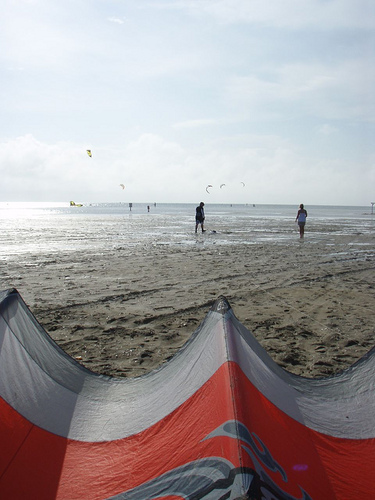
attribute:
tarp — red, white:
[1, 285, 373, 498]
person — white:
[296, 203, 307, 235]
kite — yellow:
[84, 144, 93, 156]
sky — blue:
[185, 11, 351, 168]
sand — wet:
[28, 236, 256, 260]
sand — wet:
[3, 219, 371, 383]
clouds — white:
[6, 26, 151, 104]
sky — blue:
[2, 1, 374, 204]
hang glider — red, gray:
[2, 285, 371, 495]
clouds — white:
[127, 56, 233, 133]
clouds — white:
[0, 0, 373, 207]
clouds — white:
[20, 117, 290, 183]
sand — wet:
[49, 226, 113, 258]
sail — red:
[1, 291, 374, 498]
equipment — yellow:
[63, 193, 94, 212]